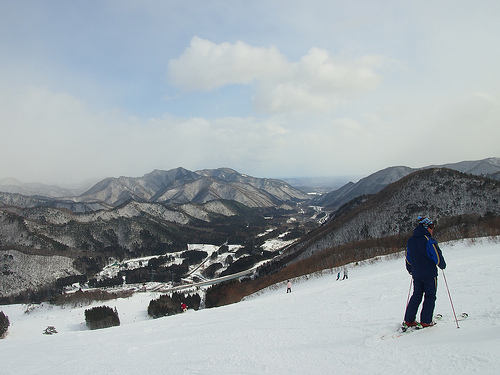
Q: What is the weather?
A: Cloudy.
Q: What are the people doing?
A: Skiing.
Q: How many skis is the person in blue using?
A: Two.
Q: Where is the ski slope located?
A: On a mountain.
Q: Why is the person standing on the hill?
A: Resting.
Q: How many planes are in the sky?
A: None.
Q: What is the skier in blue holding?
A: Ski poles.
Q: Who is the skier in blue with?
A: No one.